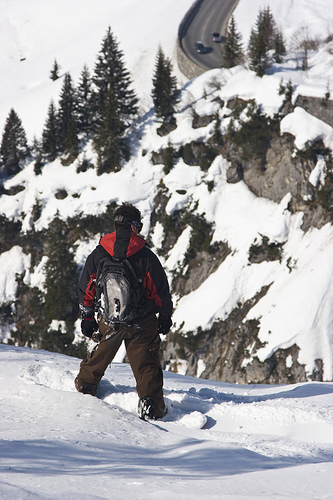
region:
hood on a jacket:
[93, 229, 147, 256]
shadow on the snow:
[93, 434, 203, 467]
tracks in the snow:
[103, 405, 149, 449]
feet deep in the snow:
[71, 368, 185, 436]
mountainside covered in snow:
[210, 289, 286, 392]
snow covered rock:
[227, 317, 263, 392]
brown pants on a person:
[74, 307, 172, 407]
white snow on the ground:
[195, 384, 300, 453]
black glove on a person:
[158, 313, 173, 332]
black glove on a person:
[76, 308, 99, 338]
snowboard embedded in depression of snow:
[3, 344, 326, 493]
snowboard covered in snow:
[61, 374, 205, 427]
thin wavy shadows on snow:
[1, 432, 284, 479]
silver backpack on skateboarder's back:
[72, 200, 169, 417]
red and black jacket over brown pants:
[72, 198, 164, 414]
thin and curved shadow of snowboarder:
[75, 198, 327, 408]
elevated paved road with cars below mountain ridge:
[2, 0, 322, 110]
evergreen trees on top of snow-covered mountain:
[0, 20, 185, 194]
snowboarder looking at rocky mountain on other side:
[34, 92, 289, 398]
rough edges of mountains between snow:
[1, 119, 322, 345]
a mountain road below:
[177, 1, 240, 76]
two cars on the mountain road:
[195, 33, 220, 53]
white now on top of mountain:
[0, 345, 329, 495]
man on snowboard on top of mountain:
[70, 202, 206, 428]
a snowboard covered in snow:
[66, 378, 205, 428]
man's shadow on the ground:
[104, 383, 331, 412]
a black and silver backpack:
[98, 259, 142, 324]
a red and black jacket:
[78, 228, 171, 318]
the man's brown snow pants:
[74, 317, 164, 413]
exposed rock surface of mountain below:
[0, 74, 330, 383]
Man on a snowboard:
[70, 199, 181, 422]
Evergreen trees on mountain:
[5, 90, 151, 192]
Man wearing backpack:
[83, 254, 153, 341]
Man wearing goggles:
[97, 206, 159, 250]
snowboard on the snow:
[68, 364, 223, 442]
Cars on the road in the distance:
[192, 29, 221, 58]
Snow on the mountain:
[176, 34, 331, 386]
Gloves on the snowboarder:
[66, 308, 103, 338]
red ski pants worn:
[79, 317, 173, 424]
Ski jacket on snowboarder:
[73, 231, 180, 342]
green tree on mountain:
[274, 26, 286, 51]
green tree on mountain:
[256, 4, 273, 48]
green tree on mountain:
[221, 14, 245, 62]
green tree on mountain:
[152, 48, 184, 119]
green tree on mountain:
[87, 85, 128, 168]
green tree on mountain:
[87, 23, 138, 123]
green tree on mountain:
[73, 61, 94, 130]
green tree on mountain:
[55, 72, 83, 150]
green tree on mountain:
[39, 100, 63, 155]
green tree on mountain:
[0, 107, 35, 165]